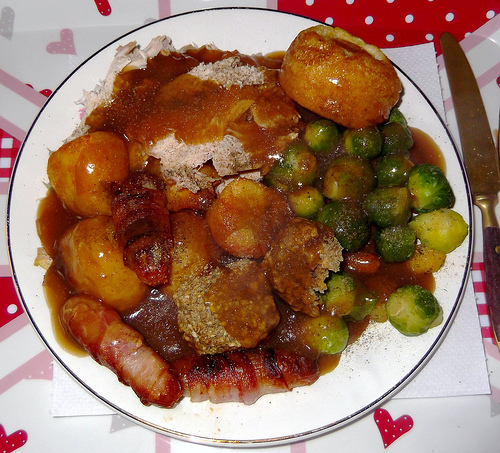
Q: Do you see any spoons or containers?
A: No, there are no containers or spoons.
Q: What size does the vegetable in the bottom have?
A: The vegetable has small size.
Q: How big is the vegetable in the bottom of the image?
A: The vegetable is small.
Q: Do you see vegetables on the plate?
A: Yes, there is a vegetable on the plate.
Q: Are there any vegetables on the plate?
A: Yes, there is a vegetable on the plate.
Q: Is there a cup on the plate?
A: No, there is a vegetable on the plate.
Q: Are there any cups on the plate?
A: No, there is a vegetable on the plate.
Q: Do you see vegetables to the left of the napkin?
A: Yes, there is a vegetable to the left of the napkin.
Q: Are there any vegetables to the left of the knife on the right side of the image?
A: Yes, there is a vegetable to the left of the knife.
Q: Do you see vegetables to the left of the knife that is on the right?
A: Yes, there is a vegetable to the left of the knife.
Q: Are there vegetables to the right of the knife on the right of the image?
A: No, the vegetable is to the left of the knife.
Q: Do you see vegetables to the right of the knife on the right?
A: No, the vegetable is to the left of the knife.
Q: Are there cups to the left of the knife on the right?
A: No, there is a vegetable to the left of the knife.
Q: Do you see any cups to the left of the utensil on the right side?
A: No, there is a vegetable to the left of the knife.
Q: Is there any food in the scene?
A: Yes, there is food.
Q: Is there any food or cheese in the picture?
A: Yes, there is food.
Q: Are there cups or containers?
A: No, there are no containers or cups.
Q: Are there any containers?
A: No, there are no containers.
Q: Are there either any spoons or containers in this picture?
A: No, there are no containers or spoons.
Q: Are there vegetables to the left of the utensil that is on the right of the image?
A: Yes, there is a vegetable to the left of the knife.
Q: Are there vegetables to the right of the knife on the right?
A: No, the vegetable is to the left of the knife.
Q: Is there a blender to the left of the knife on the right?
A: No, there is a vegetable to the left of the knife.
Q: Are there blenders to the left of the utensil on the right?
A: No, there is a vegetable to the left of the knife.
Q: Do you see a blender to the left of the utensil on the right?
A: No, there is a vegetable to the left of the knife.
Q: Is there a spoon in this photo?
A: No, there are no spoons.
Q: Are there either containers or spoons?
A: No, there are no spoons or containers.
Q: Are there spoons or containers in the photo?
A: No, there are no spoons or containers.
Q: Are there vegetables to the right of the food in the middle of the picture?
A: Yes, there is a vegetable to the right of the food.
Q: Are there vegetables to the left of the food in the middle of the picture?
A: No, the vegetable is to the right of the food.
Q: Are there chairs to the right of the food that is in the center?
A: No, there is a vegetable to the right of the food.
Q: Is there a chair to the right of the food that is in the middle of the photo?
A: No, there is a vegetable to the right of the food.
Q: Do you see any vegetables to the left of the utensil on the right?
A: Yes, there is a vegetable to the left of the knife.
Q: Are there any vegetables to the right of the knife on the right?
A: No, the vegetable is to the left of the knife.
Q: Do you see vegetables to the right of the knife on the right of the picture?
A: No, the vegetable is to the left of the knife.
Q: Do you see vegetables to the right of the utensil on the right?
A: No, the vegetable is to the left of the knife.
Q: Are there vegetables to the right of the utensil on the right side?
A: No, the vegetable is to the left of the knife.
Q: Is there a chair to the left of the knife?
A: No, there is a vegetable to the left of the knife.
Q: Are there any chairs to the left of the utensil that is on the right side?
A: No, there is a vegetable to the left of the knife.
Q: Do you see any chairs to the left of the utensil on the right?
A: No, there is a vegetable to the left of the knife.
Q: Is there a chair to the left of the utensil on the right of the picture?
A: No, there is a vegetable to the left of the knife.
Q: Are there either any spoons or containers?
A: No, there are no containers or spoons.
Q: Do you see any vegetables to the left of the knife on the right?
A: Yes, there is a vegetable to the left of the knife.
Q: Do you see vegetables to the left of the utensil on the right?
A: Yes, there is a vegetable to the left of the knife.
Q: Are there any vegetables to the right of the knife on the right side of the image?
A: No, the vegetable is to the left of the knife.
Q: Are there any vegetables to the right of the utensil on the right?
A: No, the vegetable is to the left of the knife.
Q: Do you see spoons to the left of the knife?
A: No, there is a vegetable to the left of the knife.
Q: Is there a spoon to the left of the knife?
A: No, there is a vegetable to the left of the knife.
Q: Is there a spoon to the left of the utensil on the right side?
A: No, there is a vegetable to the left of the knife.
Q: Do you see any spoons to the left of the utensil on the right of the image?
A: No, there is a vegetable to the left of the knife.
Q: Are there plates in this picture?
A: Yes, there is a plate.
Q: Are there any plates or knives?
A: Yes, there is a plate.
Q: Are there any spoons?
A: No, there are no spoons.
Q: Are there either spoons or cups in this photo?
A: No, there are no spoons or cups.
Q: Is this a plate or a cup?
A: This is a plate.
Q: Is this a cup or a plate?
A: This is a plate.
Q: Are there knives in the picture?
A: Yes, there is a knife.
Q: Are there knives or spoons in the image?
A: Yes, there is a knife.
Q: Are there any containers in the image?
A: No, there are no containers.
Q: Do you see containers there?
A: No, there are no containers.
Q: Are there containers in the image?
A: No, there are no containers.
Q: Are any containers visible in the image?
A: No, there are no containers.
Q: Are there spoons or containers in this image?
A: No, there are no containers or spoons.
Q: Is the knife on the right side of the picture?
A: Yes, the knife is on the right of the image.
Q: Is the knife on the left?
A: No, the knife is on the right of the image.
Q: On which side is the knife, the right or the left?
A: The knife is on the right of the image.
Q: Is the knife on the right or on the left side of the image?
A: The knife is on the right of the image.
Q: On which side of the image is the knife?
A: The knife is on the right of the image.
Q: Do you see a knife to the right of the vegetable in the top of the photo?
A: Yes, there is a knife to the right of the vegetable.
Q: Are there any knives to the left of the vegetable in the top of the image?
A: No, the knife is to the right of the vegetable.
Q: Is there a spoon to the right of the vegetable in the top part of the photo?
A: No, there is a knife to the right of the vegetable.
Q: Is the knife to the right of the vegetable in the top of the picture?
A: Yes, the knife is to the right of the vegetable.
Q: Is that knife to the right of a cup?
A: No, the knife is to the right of the vegetable.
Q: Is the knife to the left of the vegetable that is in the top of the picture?
A: No, the knife is to the right of the vegetable.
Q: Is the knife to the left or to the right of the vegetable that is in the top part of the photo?
A: The knife is to the right of the vegetable.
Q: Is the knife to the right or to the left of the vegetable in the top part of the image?
A: The knife is to the right of the vegetable.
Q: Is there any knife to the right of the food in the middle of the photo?
A: Yes, there is a knife to the right of the food.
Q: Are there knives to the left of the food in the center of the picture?
A: No, the knife is to the right of the food.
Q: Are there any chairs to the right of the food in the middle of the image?
A: No, there is a knife to the right of the food.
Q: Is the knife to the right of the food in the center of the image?
A: Yes, the knife is to the right of the food.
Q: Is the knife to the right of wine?
A: No, the knife is to the right of the food.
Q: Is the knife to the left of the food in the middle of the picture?
A: No, the knife is to the right of the food.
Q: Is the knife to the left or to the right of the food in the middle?
A: The knife is to the right of the food.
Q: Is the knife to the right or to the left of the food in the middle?
A: The knife is to the right of the food.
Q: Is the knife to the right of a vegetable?
A: Yes, the knife is to the right of a vegetable.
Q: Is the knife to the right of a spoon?
A: No, the knife is to the right of a vegetable.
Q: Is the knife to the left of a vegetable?
A: No, the knife is to the right of a vegetable.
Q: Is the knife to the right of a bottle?
A: No, the knife is to the right of a vegetable.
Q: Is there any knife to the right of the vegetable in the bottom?
A: Yes, there is a knife to the right of the vegetable.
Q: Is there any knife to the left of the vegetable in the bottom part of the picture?
A: No, the knife is to the right of the vegetable.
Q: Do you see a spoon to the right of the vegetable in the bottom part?
A: No, there is a knife to the right of the vegetable.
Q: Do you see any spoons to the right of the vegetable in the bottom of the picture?
A: No, there is a knife to the right of the vegetable.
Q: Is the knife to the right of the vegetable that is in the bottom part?
A: Yes, the knife is to the right of the vegetable.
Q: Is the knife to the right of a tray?
A: No, the knife is to the right of the vegetable.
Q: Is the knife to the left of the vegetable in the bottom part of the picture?
A: No, the knife is to the right of the vegetable.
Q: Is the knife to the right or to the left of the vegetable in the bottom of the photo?
A: The knife is to the right of the vegetable.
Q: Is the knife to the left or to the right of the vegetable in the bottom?
A: The knife is to the right of the vegetable.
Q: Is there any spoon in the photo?
A: No, there are no spoons.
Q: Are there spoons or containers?
A: No, there are no spoons or containers.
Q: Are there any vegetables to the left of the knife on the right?
A: Yes, there is a vegetable to the left of the knife.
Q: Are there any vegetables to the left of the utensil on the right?
A: Yes, there is a vegetable to the left of the knife.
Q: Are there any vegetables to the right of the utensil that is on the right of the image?
A: No, the vegetable is to the left of the knife.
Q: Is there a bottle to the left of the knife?
A: No, there is a vegetable to the left of the knife.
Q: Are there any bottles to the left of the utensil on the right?
A: No, there is a vegetable to the left of the knife.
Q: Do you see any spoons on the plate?
A: No, there is a vegetable on the plate.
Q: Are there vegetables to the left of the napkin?
A: Yes, there is a vegetable to the left of the napkin.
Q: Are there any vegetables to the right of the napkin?
A: No, the vegetable is to the left of the napkin.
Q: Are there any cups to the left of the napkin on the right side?
A: No, there is a vegetable to the left of the napkin.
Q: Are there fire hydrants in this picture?
A: No, there are no fire hydrants.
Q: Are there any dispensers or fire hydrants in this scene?
A: No, there are no fire hydrants or dispensers.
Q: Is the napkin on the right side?
A: Yes, the napkin is on the right of the image.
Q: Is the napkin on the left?
A: No, the napkin is on the right of the image.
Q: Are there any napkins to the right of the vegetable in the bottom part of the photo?
A: Yes, there is a napkin to the right of the vegetable.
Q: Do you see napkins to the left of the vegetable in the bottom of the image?
A: No, the napkin is to the right of the vegetable.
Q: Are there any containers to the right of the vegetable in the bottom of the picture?
A: No, there is a napkin to the right of the vegetable.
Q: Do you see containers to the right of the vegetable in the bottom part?
A: No, there is a napkin to the right of the vegetable.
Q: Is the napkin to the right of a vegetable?
A: Yes, the napkin is to the right of a vegetable.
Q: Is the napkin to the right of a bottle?
A: No, the napkin is to the right of a vegetable.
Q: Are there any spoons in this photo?
A: No, there are no spoons.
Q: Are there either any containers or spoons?
A: No, there are no spoons or containers.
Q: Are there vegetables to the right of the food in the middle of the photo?
A: Yes, there is a vegetable to the right of the food.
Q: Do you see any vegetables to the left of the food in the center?
A: No, the vegetable is to the right of the food.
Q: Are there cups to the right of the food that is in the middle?
A: No, there is a vegetable to the right of the food.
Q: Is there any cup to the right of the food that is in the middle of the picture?
A: No, there is a vegetable to the right of the food.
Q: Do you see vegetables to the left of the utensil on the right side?
A: Yes, there is a vegetable to the left of the knife.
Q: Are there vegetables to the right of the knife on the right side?
A: No, the vegetable is to the left of the knife.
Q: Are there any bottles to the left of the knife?
A: No, there is a vegetable to the left of the knife.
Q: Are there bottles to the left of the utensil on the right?
A: No, there is a vegetable to the left of the knife.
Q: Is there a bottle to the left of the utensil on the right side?
A: No, there is a vegetable to the left of the knife.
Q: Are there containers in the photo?
A: No, there are no containers.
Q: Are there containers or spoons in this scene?
A: No, there are no containers or spoons.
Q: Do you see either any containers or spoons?
A: No, there are no containers or spoons.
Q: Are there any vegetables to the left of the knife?
A: Yes, there is a vegetable to the left of the knife.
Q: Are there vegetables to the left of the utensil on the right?
A: Yes, there is a vegetable to the left of the knife.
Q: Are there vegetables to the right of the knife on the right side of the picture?
A: No, the vegetable is to the left of the knife.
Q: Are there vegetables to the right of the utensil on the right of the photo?
A: No, the vegetable is to the left of the knife.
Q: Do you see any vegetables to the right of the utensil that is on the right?
A: No, the vegetable is to the left of the knife.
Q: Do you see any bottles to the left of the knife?
A: No, there is a vegetable to the left of the knife.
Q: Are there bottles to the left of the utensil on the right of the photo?
A: No, there is a vegetable to the left of the knife.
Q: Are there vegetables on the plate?
A: Yes, there is a vegetable on the plate.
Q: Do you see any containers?
A: No, there are no containers.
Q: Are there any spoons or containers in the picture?
A: No, there are no containers or spoons.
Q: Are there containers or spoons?
A: No, there are no containers or spoons.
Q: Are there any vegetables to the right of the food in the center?
A: Yes, there is a vegetable to the right of the food.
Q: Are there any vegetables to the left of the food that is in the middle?
A: No, the vegetable is to the right of the food.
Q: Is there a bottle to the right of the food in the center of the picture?
A: No, there is a vegetable to the right of the food.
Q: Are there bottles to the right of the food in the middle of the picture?
A: No, there is a vegetable to the right of the food.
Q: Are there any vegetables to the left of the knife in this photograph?
A: Yes, there is a vegetable to the left of the knife.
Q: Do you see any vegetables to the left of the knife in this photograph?
A: Yes, there is a vegetable to the left of the knife.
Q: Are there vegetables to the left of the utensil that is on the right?
A: Yes, there is a vegetable to the left of the knife.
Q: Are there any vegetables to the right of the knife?
A: No, the vegetable is to the left of the knife.